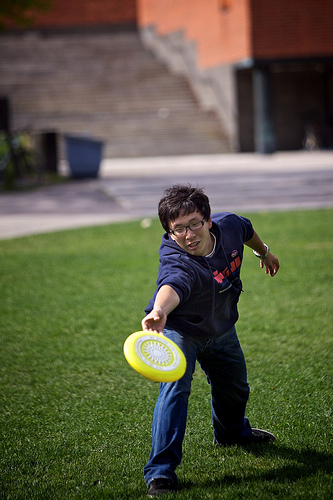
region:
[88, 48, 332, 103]
this a plain white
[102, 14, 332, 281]
looks like a flickr account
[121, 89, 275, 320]
i love this image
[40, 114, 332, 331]
this is an indoor image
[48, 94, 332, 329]
what a nice shot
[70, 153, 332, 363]
i have a flickr account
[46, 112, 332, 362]
it says a photo is nolonger available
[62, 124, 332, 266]
what a great logo indeed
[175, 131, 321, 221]
Image has a x in the middle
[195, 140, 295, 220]
Picture has a gray outline of picture frame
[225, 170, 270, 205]
X in the middle of image is gray in color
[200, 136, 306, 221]
Picture icon is in the middle of image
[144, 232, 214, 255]
This photo is not here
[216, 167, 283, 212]
the box is square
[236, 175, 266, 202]
there is an X in the center of the box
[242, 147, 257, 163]
there is a circle over the box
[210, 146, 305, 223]
the box is hanging from the circle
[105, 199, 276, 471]
A person is playing.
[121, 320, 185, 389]
A yellow Frisbee being thrown.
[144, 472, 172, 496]
the shoes are black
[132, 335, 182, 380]
design is on the frisbee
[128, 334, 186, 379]
the frisbee is yellow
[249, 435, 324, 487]
the shadow is on ground